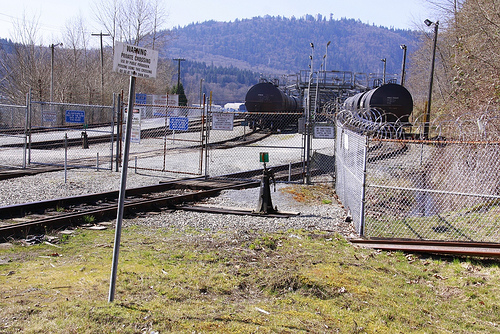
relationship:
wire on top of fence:
[317, 96, 500, 146] [326, 117, 500, 241]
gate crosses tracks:
[28, 88, 206, 186] [2, 114, 281, 178]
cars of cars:
[359, 84, 417, 138] [340, 83, 413, 137]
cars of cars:
[244, 77, 298, 135] [244, 82, 302, 135]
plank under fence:
[191, 199, 303, 224] [326, 117, 500, 241]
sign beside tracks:
[108, 36, 159, 82] [2, 114, 281, 178]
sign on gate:
[67, 107, 85, 123] [28, 88, 206, 186]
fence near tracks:
[326, 117, 500, 241] [2, 114, 281, 178]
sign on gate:
[108, 36, 159, 82] [28, 88, 206, 186]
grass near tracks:
[8, 219, 495, 333] [2, 114, 281, 178]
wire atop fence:
[317, 96, 500, 146] [326, 117, 500, 241]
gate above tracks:
[28, 88, 206, 186] [2, 114, 281, 178]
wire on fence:
[317, 96, 500, 146] [326, 117, 500, 241]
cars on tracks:
[244, 82, 302, 135] [2, 114, 281, 178]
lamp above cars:
[416, 15, 442, 143] [340, 83, 413, 137]